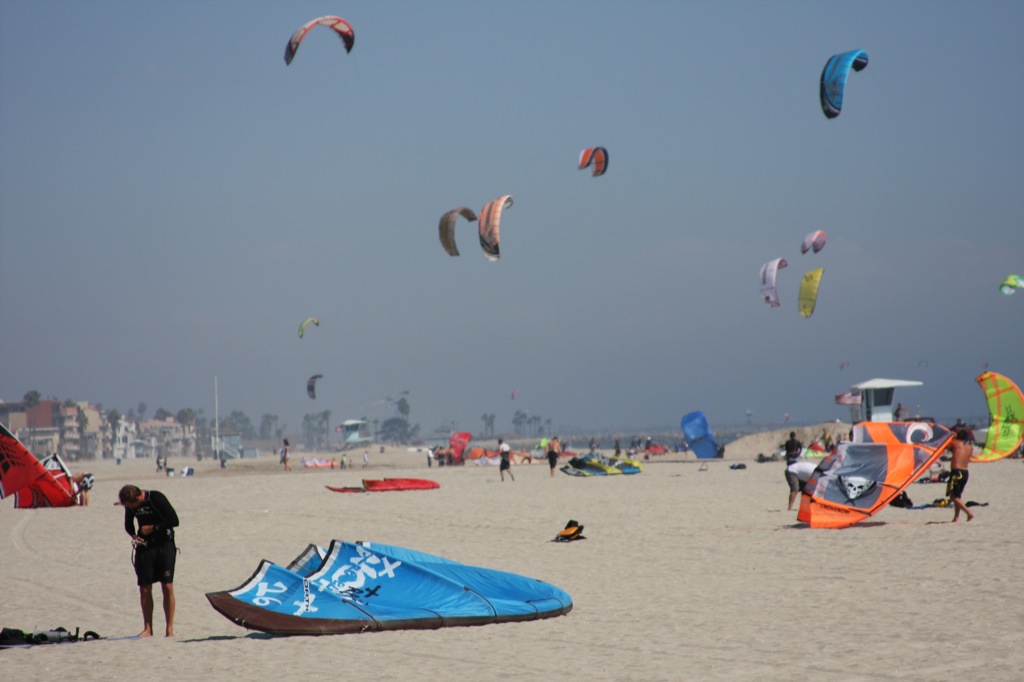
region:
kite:
[288, 17, 407, 138]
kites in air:
[433, 153, 531, 278]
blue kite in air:
[799, 17, 891, 166]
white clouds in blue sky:
[158, 140, 217, 195]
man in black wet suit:
[106, 472, 204, 634]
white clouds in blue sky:
[136, 147, 267, 249]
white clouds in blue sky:
[202, 205, 276, 256]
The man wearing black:
[106, 458, 218, 646]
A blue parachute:
[211, 534, 589, 627]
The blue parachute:
[198, 516, 607, 679]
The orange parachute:
[780, 409, 939, 543]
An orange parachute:
[788, 418, 947, 540]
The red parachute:
[0, 418, 111, 514]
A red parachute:
[0, 423, 103, 510]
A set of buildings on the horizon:
[2, 378, 252, 452]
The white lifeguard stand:
[849, 356, 916, 429]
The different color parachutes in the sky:
[239, 17, 1021, 366]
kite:
[253, 17, 368, 81]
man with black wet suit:
[101, 470, 203, 627]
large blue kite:
[798, 20, 898, 151]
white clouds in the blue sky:
[59, 169, 146, 243]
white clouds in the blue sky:
[264, 309, 316, 366]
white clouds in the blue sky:
[310, 284, 390, 332]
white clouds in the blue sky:
[142, 252, 194, 284]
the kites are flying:
[159, 0, 913, 343]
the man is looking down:
[0, 397, 200, 647]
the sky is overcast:
[156, 103, 688, 432]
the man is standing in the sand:
[81, 453, 190, 656]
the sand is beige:
[596, 514, 853, 654]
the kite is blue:
[140, 484, 594, 628]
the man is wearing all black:
[83, 415, 186, 635]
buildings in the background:
[26, 365, 344, 482]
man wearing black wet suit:
[104, 474, 194, 621]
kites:
[420, 145, 528, 263]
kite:
[800, 28, 878, 117]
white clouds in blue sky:
[205, 189, 292, 244]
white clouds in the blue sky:
[627, 286, 684, 334]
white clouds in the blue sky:
[275, 256, 352, 304]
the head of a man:
[105, 481, 154, 521]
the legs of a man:
[128, 563, 195, 639]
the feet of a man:
[122, 610, 200, 648]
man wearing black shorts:
[101, 461, 200, 632]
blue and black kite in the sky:
[805, 31, 878, 118]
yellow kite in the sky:
[792, 271, 838, 333]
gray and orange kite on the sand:
[790, 404, 952, 538]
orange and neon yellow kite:
[976, 363, 1019, 468]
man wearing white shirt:
[778, 453, 820, 504]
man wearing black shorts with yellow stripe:
[936, 423, 984, 525]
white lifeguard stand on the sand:
[852, 364, 914, 425]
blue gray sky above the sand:
[15, 9, 1022, 430]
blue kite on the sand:
[678, 417, 724, 456]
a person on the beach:
[933, 358, 1020, 486]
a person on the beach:
[462, 432, 520, 472]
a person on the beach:
[535, 434, 578, 474]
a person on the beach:
[535, 417, 599, 522]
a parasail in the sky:
[421, 203, 467, 273]